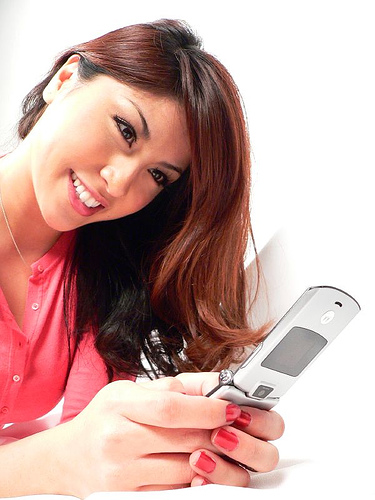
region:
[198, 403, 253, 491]
red polish on a woman's nails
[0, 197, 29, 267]
a thin silver necklace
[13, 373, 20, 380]
a tiny pink blouse button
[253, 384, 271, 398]
the camera window on a phone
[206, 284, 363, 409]
a flip top razr cell phone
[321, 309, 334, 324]
the motorola symbol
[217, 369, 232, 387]
a flip top phone hinge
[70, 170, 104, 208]
white teeth on a woman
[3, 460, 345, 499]
a white blanket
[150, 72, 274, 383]
light brown highlights in a woman's hair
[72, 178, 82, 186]
white colored human tooth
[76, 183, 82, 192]
white colored human tooth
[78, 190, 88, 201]
white colored human tooth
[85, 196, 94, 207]
white colored human tooth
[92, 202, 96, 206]
white colored human tooth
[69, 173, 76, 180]
white colored human tooth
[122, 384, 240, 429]
white colored human finger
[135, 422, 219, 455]
white colored human finger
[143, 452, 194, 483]
white colored human finger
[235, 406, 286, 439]
white colored human finger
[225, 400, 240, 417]
the red fingernail of a person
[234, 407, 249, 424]
the red fingernail of a person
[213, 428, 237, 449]
the red fingernail of a person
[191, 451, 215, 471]
the red fingernail of a person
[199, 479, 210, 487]
the red fingernail of a person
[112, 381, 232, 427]
the finger of a hand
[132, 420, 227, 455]
the finger of a hand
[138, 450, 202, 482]
the finger of a hand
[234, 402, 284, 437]
the finger of a hand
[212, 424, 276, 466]
the finger of a hand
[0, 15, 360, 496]
girl with long hair holding phone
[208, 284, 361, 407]
phone being held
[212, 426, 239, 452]
nail polish on a finger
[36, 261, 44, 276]
unbuttoned top button of shirt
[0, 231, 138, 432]
pink shirt worn by girl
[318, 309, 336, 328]
circle logo on phone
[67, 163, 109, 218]
smile on girl's face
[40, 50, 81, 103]
the girl's ear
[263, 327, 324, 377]
grey window on phone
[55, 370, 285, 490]
hands that are holding the phone